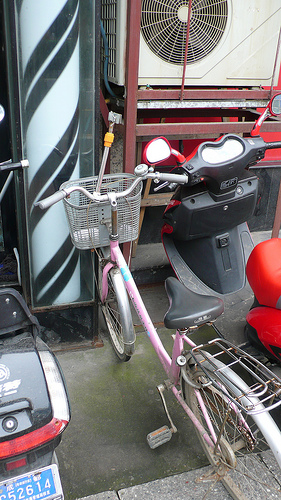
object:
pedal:
[146, 425, 171, 452]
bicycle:
[33, 159, 279, 497]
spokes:
[107, 304, 123, 329]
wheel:
[95, 260, 132, 366]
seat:
[161, 273, 224, 329]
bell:
[133, 163, 153, 178]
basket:
[59, 171, 142, 250]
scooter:
[143, 90, 280, 375]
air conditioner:
[102, 0, 281, 89]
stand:
[96, 3, 279, 275]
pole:
[13, 1, 94, 310]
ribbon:
[20, 0, 78, 142]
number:
[43, 475, 55, 493]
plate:
[0, 458, 63, 495]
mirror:
[145, 137, 171, 163]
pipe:
[93, 107, 122, 199]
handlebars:
[38, 188, 65, 210]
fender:
[195, 346, 281, 467]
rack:
[189, 334, 280, 413]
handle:
[156, 172, 187, 184]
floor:
[60, 273, 219, 500]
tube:
[95, 111, 123, 194]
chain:
[229, 420, 254, 452]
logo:
[220, 176, 238, 190]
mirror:
[269, 90, 281, 120]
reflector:
[150, 425, 167, 437]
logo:
[120, 267, 129, 284]